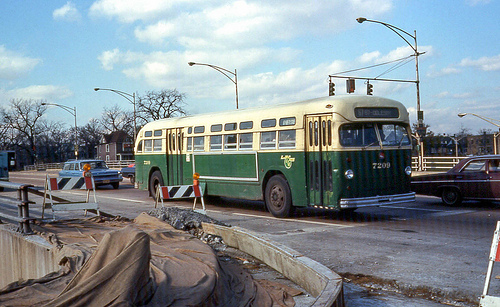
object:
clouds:
[81, 0, 193, 23]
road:
[394, 221, 457, 268]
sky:
[1, 2, 71, 30]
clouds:
[15, 84, 58, 98]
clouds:
[0, 53, 48, 71]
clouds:
[92, 46, 141, 70]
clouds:
[186, 50, 258, 71]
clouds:
[389, 50, 407, 57]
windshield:
[338, 122, 411, 148]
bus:
[133, 94, 419, 218]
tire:
[265, 174, 291, 218]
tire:
[150, 170, 164, 202]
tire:
[441, 188, 463, 208]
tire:
[130, 176, 135, 184]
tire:
[111, 181, 120, 189]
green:
[218, 160, 245, 171]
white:
[227, 114, 252, 121]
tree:
[0, 97, 47, 165]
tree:
[99, 104, 134, 136]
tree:
[133, 87, 192, 121]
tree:
[31, 117, 68, 162]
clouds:
[133, 18, 186, 46]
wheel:
[265, 173, 292, 217]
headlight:
[404, 166, 411, 175]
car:
[410, 154, 500, 206]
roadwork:
[77, 191, 344, 235]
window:
[144, 131, 152, 153]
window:
[260, 119, 277, 150]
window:
[222, 123, 237, 151]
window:
[210, 124, 223, 151]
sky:
[454, 92, 500, 107]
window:
[278, 116, 297, 150]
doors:
[304, 112, 333, 208]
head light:
[344, 169, 354, 179]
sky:
[149, 17, 198, 42]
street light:
[458, 113, 466, 118]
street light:
[356, 17, 367, 24]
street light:
[188, 62, 196, 67]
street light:
[94, 88, 99, 92]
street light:
[41, 103, 46, 106]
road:
[10, 171, 43, 184]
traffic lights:
[329, 83, 335, 96]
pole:
[416, 56, 421, 111]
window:
[193, 126, 204, 152]